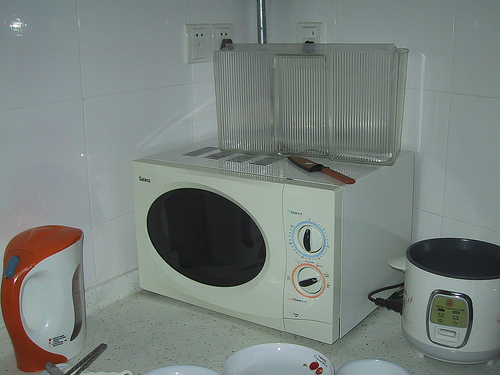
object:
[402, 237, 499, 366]
slow cooker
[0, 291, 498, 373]
counter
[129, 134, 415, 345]
microwave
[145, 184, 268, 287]
window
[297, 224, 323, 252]
control knob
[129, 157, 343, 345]
microwave's door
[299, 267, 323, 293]
control knob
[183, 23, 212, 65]
electrical outlet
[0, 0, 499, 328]
wall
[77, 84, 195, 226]
tile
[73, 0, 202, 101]
tile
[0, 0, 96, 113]
tile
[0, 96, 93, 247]
tile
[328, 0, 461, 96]
tile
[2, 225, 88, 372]
pitcher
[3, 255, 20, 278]
button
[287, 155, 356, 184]
knife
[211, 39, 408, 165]
case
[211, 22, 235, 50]
electrical outlet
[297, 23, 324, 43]
electrical outlet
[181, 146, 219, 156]
vent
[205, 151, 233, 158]
vent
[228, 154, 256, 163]
vent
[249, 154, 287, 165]
vent